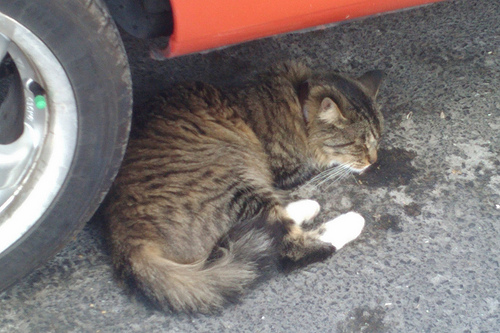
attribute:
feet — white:
[276, 194, 326, 225]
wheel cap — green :
[4, 31, 97, 193]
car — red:
[15, 0, 462, 60]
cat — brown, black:
[138, 42, 451, 297]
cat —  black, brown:
[103, 58, 377, 308]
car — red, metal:
[2, 2, 484, 66]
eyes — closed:
[348, 146, 363, 156]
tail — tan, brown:
[126, 229, 276, 315]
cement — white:
[423, 107, 489, 232]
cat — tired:
[103, 66, 448, 305]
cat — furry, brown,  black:
[105, 57, 417, 309]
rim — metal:
[1, 12, 78, 254]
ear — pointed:
[316, 94, 348, 127]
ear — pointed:
[358, 67, 387, 102]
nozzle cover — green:
[31, 91, 49, 113]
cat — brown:
[141, 64, 370, 279]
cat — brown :
[110, 45, 392, 310]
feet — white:
[275, 190, 378, 263]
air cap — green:
[26, 74, 49, 113]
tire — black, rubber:
[8, 0, 128, 291]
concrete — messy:
[11, 24, 496, 324]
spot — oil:
[357, 128, 417, 191]